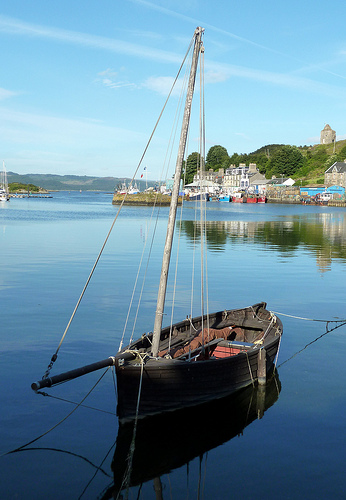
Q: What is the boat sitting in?
A: Some water.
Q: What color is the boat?
A: Its black.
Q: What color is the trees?
A: Pretty green.